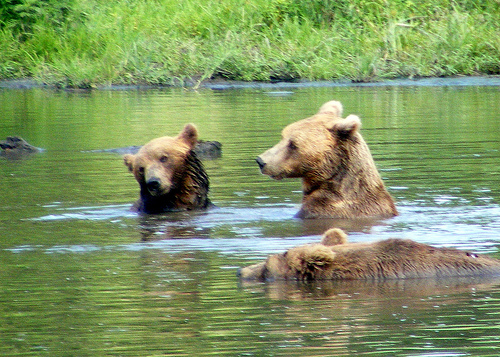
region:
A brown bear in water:
[255, 101, 401, 220]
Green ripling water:
[0, 71, 499, 355]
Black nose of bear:
[146, 176, 161, 192]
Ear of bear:
[180, 124, 197, 145]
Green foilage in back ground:
[0, 0, 499, 85]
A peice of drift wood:
[0, 134, 222, 159]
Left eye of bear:
[158, 155, 169, 164]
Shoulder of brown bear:
[287, 188, 349, 218]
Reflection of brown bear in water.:
[230, 279, 498, 354]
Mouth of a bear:
[261, 169, 286, 179]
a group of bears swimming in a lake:
[103, 103, 493, 304]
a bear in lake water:
[251, 88, 408, 222]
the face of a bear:
[108, 118, 206, 203]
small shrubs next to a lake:
[76, 13, 185, 115]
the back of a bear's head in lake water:
[1, 123, 43, 164]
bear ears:
[316, 89, 370, 138]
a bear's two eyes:
[133, 153, 173, 173]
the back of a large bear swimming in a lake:
[211, 228, 496, 314]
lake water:
[8, 258, 123, 339]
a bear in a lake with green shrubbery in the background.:
[230, 3, 420, 223]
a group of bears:
[105, 103, 487, 293]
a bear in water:
[117, 134, 203, 262]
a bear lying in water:
[222, 226, 499, 298]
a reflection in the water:
[53, 218, 239, 330]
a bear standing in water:
[255, 101, 407, 232]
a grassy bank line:
[119, 36, 497, 93]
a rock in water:
[4, 121, 43, 170]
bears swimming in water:
[29, 9, 490, 326]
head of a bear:
[122, 121, 203, 203]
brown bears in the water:
[117, 68, 499, 288]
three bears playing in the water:
[123, 100, 495, 302]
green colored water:
[6, 89, 497, 354]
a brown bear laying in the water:
[238, 228, 498, 303]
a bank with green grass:
[1, 4, 497, 87]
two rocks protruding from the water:
[2, 133, 224, 159]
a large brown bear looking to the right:
[253, 101, 401, 224]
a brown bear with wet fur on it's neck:
[121, 121, 214, 213]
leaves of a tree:
[4, 3, 84, 43]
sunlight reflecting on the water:
[6, 150, 498, 260]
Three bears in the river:
[27, 30, 440, 355]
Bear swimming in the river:
[226, 230, 475, 312]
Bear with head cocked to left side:
[100, 128, 221, 209]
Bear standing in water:
[249, 99, 404, 219]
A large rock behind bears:
[88, 125, 233, 157]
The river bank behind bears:
[11, 66, 473, 92]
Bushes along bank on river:
[36, 23, 464, 93]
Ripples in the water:
[210, 187, 480, 242]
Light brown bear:
[286, 117, 379, 209]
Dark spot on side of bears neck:
[176, 141, 210, 207]